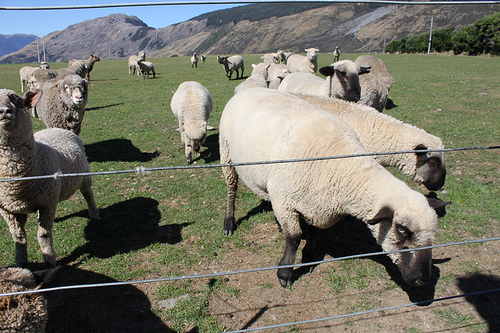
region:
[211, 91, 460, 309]
two bright white sheep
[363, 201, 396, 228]
one pointy black sheep ear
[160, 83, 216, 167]
sheep looking down at the grass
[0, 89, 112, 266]
fluffy sheep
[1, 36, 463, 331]
a herd of sheep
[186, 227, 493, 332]
a patch of brown in the green grass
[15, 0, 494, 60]
a dark mountain range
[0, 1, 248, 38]
bright blue sky with not a cloud in sight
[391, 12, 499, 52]
green shrubbery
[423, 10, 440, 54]
tall and skinny silver pole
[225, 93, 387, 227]
a white sheep eating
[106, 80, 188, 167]
clear green grass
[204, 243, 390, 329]
brown soil on ground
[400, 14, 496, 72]
green trees in background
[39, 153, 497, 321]
a grey wired fence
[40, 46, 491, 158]
a big flock of sheep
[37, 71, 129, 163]
a very woolly sheep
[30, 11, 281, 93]
a big mountain in background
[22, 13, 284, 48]
bright clear blue sky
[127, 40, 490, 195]
flock of sheep eating grass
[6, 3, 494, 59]
Mountains in the background.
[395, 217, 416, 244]
Sheep's left eye.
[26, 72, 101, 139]
Gray coated sheep in middle of shot.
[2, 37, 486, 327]
Small herd of sheep.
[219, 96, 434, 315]
Sheep looking for things to eat.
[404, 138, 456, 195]
Face of a sheep.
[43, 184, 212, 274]
Shadow of a sheep.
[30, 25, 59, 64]
Powerline poles in background.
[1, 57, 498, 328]
Green grassland.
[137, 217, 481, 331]
Small patch of dirt.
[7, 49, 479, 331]
many sheep in photo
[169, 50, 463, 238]
many white sheep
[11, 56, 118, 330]
many grey sheep in photo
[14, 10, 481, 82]
mountains in background of photo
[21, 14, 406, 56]
mountains have no trees on them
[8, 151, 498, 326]
sheep behind grey fence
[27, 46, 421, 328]
many sheep on green grass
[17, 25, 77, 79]
wooden poles in background of photo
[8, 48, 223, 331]
sheep cashing shadows on grass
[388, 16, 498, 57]
line of trees off to right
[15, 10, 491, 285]
a group of sheep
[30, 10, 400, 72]
foothills rising in the background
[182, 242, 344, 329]
worn in grass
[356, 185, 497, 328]
an electric fence guarding livestock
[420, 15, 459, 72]
a power post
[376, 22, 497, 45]
a copse of green, leafy trees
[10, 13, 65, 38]
a cloudless blue sky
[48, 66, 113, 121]
a sheep in need of shearing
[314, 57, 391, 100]
a sheep with a black nose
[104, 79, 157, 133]
green, short grass